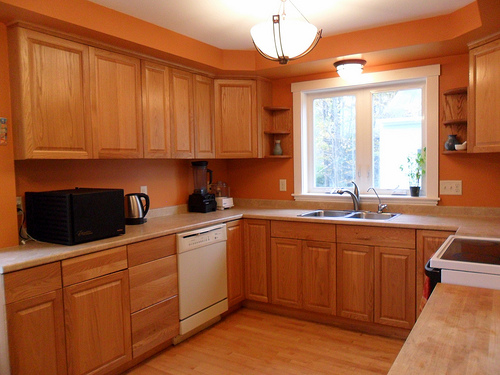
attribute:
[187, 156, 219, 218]
blender — black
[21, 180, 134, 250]
microwave — black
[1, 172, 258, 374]
counter — marbled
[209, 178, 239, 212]
processor — white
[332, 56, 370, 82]
light — on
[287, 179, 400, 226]
sink — chrome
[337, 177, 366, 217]
faucet — chrome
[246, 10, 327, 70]
shade — white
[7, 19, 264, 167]
cabinets — wood, hanging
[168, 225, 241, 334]
dishwasher — white